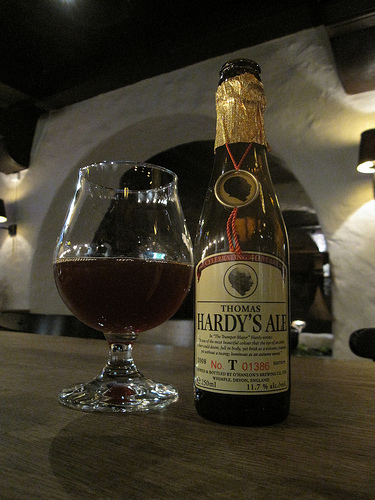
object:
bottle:
[193, 58, 291, 426]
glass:
[54, 161, 196, 414]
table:
[1, 327, 375, 500]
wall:
[283, 49, 312, 75]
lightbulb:
[356, 128, 375, 175]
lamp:
[355, 128, 375, 175]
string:
[226, 144, 237, 169]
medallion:
[214, 167, 260, 207]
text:
[208, 313, 235, 346]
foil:
[234, 94, 252, 104]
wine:
[75, 253, 130, 278]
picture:
[228, 266, 253, 296]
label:
[193, 251, 289, 394]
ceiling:
[12, 30, 91, 72]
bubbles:
[71, 255, 105, 261]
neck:
[216, 107, 265, 148]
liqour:
[225, 163, 263, 172]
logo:
[196, 312, 262, 333]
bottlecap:
[219, 56, 260, 74]